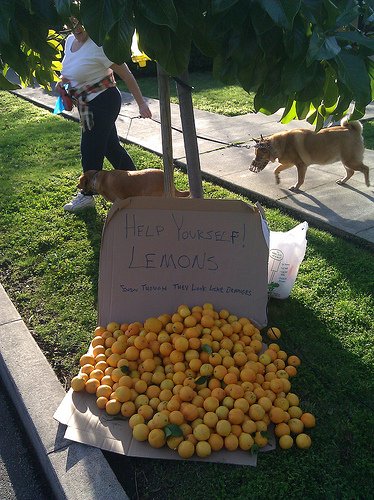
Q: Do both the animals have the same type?
A: Yes, all the animals are dogs.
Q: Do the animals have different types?
A: No, all the animals are dogs.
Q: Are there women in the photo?
A: Yes, there is a woman.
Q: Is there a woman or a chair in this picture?
A: Yes, there is a woman.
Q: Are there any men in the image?
A: No, there are no men.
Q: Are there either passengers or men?
A: No, there are no men or passengers.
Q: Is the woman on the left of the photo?
A: Yes, the woman is on the left of the image.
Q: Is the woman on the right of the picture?
A: No, the woman is on the left of the image.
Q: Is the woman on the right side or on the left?
A: The woman is on the left of the image.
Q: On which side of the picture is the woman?
A: The woman is on the left of the image.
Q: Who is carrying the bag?
A: The woman is carrying the bag.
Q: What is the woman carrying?
A: The woman is carrying a bag.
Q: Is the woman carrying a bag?
A: Yes, the woman is carrying a bag.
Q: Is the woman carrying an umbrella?
A: No, the woman is carrying a bag.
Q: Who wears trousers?
A: The woman wears trousers.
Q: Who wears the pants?
A: The woman wears trousers.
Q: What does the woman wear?
A: The woman wears pants.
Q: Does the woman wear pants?
A: Yes, the woman wears pants.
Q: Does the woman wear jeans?
A: No, the woman wears pants.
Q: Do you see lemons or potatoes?
A: Yes, there is a lemon.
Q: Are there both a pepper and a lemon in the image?
A: No, there is a lemon but no peppers.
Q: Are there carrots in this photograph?
A: No, there are no carrots.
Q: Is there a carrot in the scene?
A: No, there are no carrots.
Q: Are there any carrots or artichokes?
A: No, there are no carrots or artichokes.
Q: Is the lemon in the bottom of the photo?
A: Yes, the lemon is in the bottom of the image.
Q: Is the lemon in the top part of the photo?
A: No, the lemon is in the bottom of the image.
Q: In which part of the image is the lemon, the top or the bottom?
A: The lemon is in the bottom of the image.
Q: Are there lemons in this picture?
A: Yes, there are lemons.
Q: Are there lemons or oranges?
A: Yes, there are lemons.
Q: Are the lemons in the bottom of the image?
A: Yes, the lemons are in the bottom of the image.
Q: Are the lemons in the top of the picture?
A: No, the lemons are in the bottom of the image.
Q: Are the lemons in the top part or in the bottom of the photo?
A: The lemons are in the bottom of the image.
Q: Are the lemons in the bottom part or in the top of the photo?
A: The lemons are in the bottom of the image.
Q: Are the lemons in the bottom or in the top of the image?
A: The lemons are in the bottom of the image.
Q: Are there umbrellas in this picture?
A: No, there are no umbrellas.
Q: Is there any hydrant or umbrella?
A: No, there are no umbrellas or fire hydrants.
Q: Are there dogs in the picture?
A: Yes, there is a dog.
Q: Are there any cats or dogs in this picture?
A: Yes, there is a dog.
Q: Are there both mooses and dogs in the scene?
A: No, there is a dog but no mooses.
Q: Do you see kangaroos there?
A: No, there are no kangaroos.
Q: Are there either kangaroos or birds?
A: No, there are no kangaroos or birds.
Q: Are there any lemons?
A: Yes, there are lemons.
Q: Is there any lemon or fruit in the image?
A: Yes, there are lemons.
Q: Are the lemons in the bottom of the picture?
A: Yes, the lemons are in the bottom of the image.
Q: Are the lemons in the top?
A: No, the lemons are in the bottom of the image.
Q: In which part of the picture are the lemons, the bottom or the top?
A: The lemons are in the bottom of the image.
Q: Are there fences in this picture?
A: No, there are no fences.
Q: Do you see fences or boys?
A: No, there are no fences or boys.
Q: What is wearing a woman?
A: The shirt is wearing a woman.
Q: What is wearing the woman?
A: The shirt is wearing a woman.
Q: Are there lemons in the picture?
A: Yes, there are lemons.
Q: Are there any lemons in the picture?
A: Yes, there are lemons.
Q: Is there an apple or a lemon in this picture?
A: Yes, there are lemons.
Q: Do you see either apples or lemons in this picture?
A: Yes, there are lemons.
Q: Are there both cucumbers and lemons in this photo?
A: No, there are lemons but no cucumbers.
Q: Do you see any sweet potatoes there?
A: No, there are no sweet potatoes.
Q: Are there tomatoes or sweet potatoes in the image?
A: No, there are no sweet potatoes or tomatoes.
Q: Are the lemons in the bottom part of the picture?
A: Yes, the lemons are in the bottom of the image.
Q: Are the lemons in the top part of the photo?
A: No, the lemons are in the bottom of the image.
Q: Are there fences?
A: No, there are no fences.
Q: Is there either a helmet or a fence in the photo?
A: No, there are no fences or helmets.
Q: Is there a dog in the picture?
A: Yes, there is a dog.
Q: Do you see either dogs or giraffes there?
A: Yes, there is a dog.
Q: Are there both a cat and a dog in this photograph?
A: No, there is a dog but no cats.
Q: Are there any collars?
A: No, there are no collars.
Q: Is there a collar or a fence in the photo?
A: No, there are no collars or fences.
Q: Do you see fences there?
A: No, there are no fences.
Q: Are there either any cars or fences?
A: No, there are no fences or cars.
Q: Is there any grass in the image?
A: Yes, there is grass.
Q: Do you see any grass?
A: Yes, there is grass.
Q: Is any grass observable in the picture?
A: Yes, there is grass.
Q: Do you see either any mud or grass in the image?
A: Yes, there is grass.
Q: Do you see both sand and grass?
A: No, there is grass but no sand.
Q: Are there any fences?
A: No, there are no fences.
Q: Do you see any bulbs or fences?
A: No, there are no fences or bulbs.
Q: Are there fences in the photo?
A: No, there are no fences.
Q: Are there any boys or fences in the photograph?
A: No, there are no fences or boys.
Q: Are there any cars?
A: No, there are no cars.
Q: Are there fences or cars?
A: No, there are no cars or fences.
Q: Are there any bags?
A: Yes, there is a bag.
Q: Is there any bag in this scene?
A: Yes, there is a bag.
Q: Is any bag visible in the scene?
A: Yes, there is a bag.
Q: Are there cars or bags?
A: Yes, there is a bag.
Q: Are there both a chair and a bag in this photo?
A: No, there is a bag but no chairs.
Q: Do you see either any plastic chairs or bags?
A: Yes, there is a plastic bag.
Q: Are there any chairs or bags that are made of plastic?
A: Yes, the bag is made of plastic.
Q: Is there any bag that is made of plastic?
A: Yes, there is a bag that is made of plastic.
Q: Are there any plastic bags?
A: Yes, there is a bag that is made of plastic.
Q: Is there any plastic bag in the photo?
A: Yes, there is a bag that is made of plastic.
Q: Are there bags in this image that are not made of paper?
A: Yes, there is a bag that is made of plastic.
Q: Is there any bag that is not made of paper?
A: Yes, there is a bag that is made of plastic.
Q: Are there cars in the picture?
A: No, there are no cars.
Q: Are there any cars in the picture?
A: No, there are no cars.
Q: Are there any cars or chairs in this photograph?
A: No, there are no cars or chairs.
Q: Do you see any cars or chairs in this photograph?
A: No, there are no cars or chairs.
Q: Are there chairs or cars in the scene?
A: No, there are no cars or chairs.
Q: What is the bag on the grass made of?
A: The bag is made of plastic.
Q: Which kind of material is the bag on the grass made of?
A: The bag is made of plastic.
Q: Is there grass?
A: Yes, there is grass.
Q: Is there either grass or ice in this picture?
A: Yes, there is grass.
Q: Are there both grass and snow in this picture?
A: No, there is grass but no snow.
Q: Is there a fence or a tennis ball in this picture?
A: No, there are no fences or tennis balls.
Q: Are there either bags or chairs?
A: Yes, there is a bag.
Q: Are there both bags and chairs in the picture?
A: No, there is a bag but no chairs.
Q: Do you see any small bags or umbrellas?
A: Yes, there is a small bag.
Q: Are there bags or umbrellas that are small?
A: Yes, the bag is small.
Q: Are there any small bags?
A: Yes, there is a small bag.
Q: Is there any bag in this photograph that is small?
A: Yes, there is a bag that is small.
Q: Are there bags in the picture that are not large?
A: Yes, there is a small bag.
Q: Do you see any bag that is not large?
A: Yes, there is a small bag.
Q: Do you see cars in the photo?
A: No, there are no cars.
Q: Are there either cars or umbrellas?
A: No, there are no cars or umbrellas.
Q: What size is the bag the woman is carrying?
A: The bag is small.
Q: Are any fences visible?
A: No, there are no fences.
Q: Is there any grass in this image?
A: Yes, there is grass.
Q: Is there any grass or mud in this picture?
A: Yes, there is grass.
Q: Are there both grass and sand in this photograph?
A: No, there is grass but no sand.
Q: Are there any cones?
A: No, there are no cones.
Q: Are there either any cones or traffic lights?
A: No, there are no cones or traffic lights.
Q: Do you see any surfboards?
A: No, there are no surfboards.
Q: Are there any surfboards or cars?
A: No, there are no surfboards or cars.